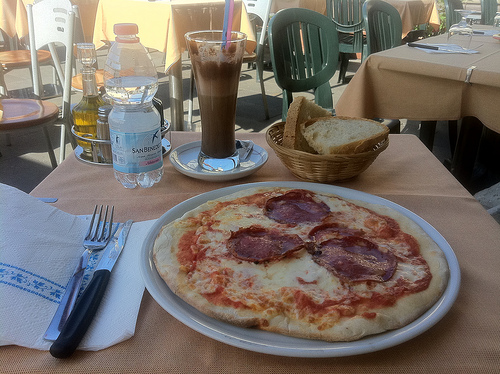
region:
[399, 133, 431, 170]
brown fabric on cloth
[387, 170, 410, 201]
brown fabric on cloth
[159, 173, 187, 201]
brown fabric on cloth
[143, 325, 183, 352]
brown fabric on cloth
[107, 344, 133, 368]
brown fabric on cloth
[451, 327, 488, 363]
brown fabric on cloth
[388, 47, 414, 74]
brown fabric on cloth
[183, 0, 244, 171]
Partially-consumed chocolate drink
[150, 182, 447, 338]
Pizza with thin meat slices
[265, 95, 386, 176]
Bread slices in wicker basket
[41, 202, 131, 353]
Silverware consisting of knife and fork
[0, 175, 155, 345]
Paper napkin under silverware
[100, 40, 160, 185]
Partially-consumed bottle of water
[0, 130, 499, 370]
Beige tablecloth covers table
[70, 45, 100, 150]
Oil (or vinegar) dispenser in condiment caddy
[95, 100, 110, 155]
Pepper shaker in condiment caddy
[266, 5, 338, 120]
Green chair at next table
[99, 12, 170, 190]
a bottle of water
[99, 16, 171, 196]
bottle has pink cap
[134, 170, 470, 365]
a pizza over a dish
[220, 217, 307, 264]
a sausage on pizza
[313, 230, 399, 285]
a sausage on pizza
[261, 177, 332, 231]
a sausage on pizza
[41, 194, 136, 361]
a knife and a fork over a napkin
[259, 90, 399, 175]
a basket of bread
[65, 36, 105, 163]
a bottle of oil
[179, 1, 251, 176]
a blue and pink straw in a glass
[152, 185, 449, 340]
the pizza on the plate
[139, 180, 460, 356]
the white plate under the pizza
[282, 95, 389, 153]
the bread in the basket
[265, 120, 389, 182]
the basket holding the bread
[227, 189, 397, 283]
the pepperoni on the pizza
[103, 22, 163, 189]
the plastic bottle on the table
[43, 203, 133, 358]
the utensils on the napkin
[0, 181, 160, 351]
the napkins under the utensils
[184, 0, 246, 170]
the large cup filled with brown liquid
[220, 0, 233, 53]
the straws in the cup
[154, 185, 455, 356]
a pizza on a plate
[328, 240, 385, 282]
pepperoni on the pizza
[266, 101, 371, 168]
a basket on the table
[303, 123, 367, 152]
bread in the basket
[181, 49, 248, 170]
a glass on the table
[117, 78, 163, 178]
a water bottle on the table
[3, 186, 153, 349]
a napkin on the table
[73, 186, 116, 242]
a fork on the table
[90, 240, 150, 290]
a knife on the table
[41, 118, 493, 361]
a table cloth